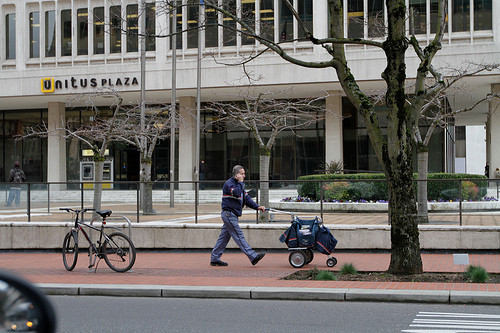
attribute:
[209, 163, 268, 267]
man — talking, speaking, here, walking, mail man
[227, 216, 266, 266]
leg — in front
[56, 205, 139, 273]
bike — black, here, parked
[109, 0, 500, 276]
tree — here, branchy, leafless, tall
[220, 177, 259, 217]
jacket — blue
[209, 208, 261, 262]
pants — grey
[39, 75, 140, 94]
sign — black, unitus plaza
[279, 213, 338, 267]
mail stroller — blue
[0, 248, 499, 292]
sidewalk — red brick, red, brick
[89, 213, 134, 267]
post — metal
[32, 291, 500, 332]
road — black, asphalt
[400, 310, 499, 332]
lettering — white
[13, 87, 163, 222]
tree — leafless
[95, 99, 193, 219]
tree — leafless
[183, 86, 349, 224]
tree — leafless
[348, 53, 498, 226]
tree — leafless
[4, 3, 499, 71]
windows — thin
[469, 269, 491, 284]
plant — short, small, green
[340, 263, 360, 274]
plant — short, green, small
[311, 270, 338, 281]
plant — green, small, short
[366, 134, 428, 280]
trunk — moss covered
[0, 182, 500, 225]
fence — metal, glass